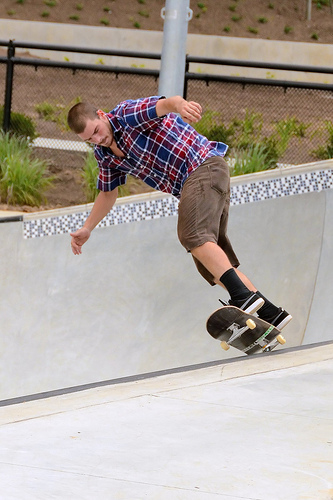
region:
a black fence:
[4, 27, 329, 127]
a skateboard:
[194, 269, 302, 376]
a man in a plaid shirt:
[35, 89, 250, 226]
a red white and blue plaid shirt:
[81, 102, 265, 226]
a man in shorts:
[53, 86, 255, 286]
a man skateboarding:
[43, 100, 304, 391]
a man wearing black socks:
[63, 99, 298, 366]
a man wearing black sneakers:
[57, 97, 281, 324]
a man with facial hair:
[46, 104, 129, 175]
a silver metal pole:
[134, 0, 211, 124]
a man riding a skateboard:
[57, 85, 291, 360]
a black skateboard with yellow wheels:
[196, 303, 283, 360]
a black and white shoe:
[221, 291, 263, 314]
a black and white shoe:
[263, 302, 295, 333]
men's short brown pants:
[171, 153, 239, 284]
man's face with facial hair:
[62, 98, 115, 149]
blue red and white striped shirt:
[80, 93, 228, 200]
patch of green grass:
[0, 132, 52, 210]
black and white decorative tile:
[19, 161, 330, 244]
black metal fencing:
[0, 32, 332, 166]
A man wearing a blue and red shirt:
[57, 84, 297, 329]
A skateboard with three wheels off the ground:
[201, 294, 284, 370]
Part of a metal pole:
[151, 1, 196, 109]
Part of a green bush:
[1, 126, 55, 215]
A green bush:
[228, 144, 276, 177]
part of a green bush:
[83, 151, 130, 205]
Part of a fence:
[190, 60, 332, 167]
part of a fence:
[0, 41, 159, 194]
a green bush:
[274, 115, 316, 142]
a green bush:
[32, 87, 63, 128]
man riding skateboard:
[62, 93, 293, 328]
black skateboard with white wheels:
[205, 305, 284, 354]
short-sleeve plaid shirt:
[90, 95, 227, 190]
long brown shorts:
[175, 152, 241, 281]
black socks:
[220, 267, 276, 310]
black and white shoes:
[217, 291, 290, 329]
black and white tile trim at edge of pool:
[22, 165, 330, 236]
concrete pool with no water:
[0, 158, 328, 401]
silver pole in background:
[158, 0, 189, 104]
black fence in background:
[1, 38, 331, 168]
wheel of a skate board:
[240, 322, 260, 331]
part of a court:
[194, 458, 200, 478]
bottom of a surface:
[217, 430, 224, 444]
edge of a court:
[279, 438, 294, 454]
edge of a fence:
[262, 72, 276, 98]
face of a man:
[100, 111, 108, 137]